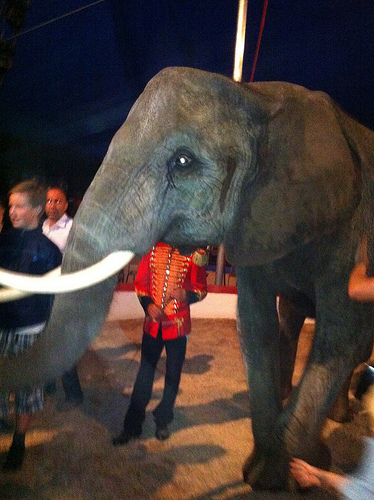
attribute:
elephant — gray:
[8, 64, 355, 404]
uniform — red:
[141, 242, 208, 369]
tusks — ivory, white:
[3, 232, 130, 298]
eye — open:
[171, 147, 202, 173]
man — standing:
[45, 177, 98, 407]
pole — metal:
[223, 2, 253, 78]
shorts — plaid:
[5, 325, 56, 420]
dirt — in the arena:
[87, 436, 220, 492]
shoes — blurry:
[100, 418, 176, 452]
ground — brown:
[74, 311, 286, 498]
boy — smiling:
[2, 177, 94, 476]